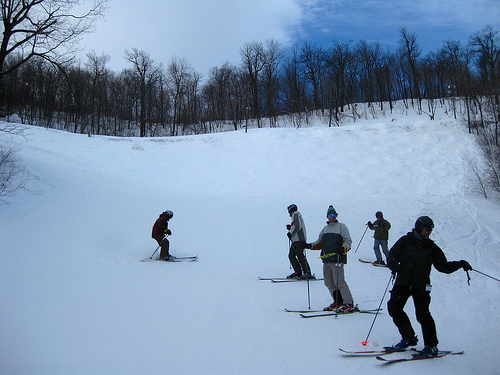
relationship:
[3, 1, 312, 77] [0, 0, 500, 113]
clouds in blue sky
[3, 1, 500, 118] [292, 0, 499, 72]
clouds in blue sky